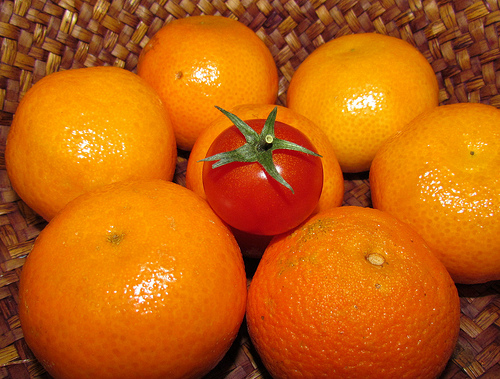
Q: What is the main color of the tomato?
A: Red.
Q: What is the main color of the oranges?
A: Orange.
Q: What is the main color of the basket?
A: Brown.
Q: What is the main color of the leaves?
A: Green.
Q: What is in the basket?
A: Fruit.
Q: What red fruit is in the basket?
A: Tomato.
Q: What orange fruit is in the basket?
A: Oranges.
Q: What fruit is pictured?
A: Oranges.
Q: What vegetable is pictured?
A: A tomato.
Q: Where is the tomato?
A: On top of the oranges.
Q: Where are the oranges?
A: In a basket.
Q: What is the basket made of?
A: Natural fibers.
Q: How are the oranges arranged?
A: In a circle.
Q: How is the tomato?
A: Ripe.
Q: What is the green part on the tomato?
A: Leaves.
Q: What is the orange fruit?
A: Oranges.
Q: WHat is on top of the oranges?
A: Tomato.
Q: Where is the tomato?
A: On the oranges.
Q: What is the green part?
A: Stem.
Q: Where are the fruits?
A: In a basket.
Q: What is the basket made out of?
A: Straw.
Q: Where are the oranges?
A: Beneath the tomato.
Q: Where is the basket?
A: Under the fruits.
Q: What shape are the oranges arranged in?
A: A circle.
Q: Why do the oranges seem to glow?
A: They are shiny.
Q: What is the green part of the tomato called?
A: Stem.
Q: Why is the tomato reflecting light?
A: It is shiny.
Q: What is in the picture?
A: Oranges and a tomato.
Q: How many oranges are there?
A: Seven.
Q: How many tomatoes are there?
A: One.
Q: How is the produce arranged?
A: In a circle.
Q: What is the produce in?
A: A basket.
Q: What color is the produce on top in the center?
A: Red.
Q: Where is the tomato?
A: On top of the oranges.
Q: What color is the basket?
A: Brown.